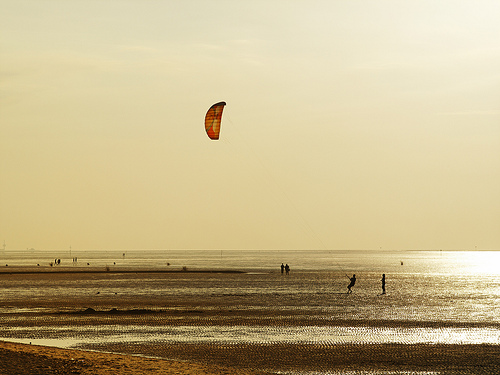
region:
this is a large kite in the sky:
[195, 60, 375, 334]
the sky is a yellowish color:
[0, 2, 494, 249]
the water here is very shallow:
[26, 235, 439, 335]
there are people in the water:
[0, 233, 437, 333]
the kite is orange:
[190, 68, 247, 167]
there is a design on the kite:
[191, 95, 250, 152]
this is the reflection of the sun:
[435, 243, 499, 344]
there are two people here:
[271, 253, 306, 297]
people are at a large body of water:
[3, 235, 473, 371]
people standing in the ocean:
[10, 243, 447, 315]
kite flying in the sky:
[196, 95, 238, 154]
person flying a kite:
[341, 270, 362, 305]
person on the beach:
[375, 269, 391, 300]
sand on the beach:
[29, 348, 91, 373]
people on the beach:
[275, 257, 307, 284]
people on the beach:
[50, 253, 62, 270]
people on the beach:
[65, 254, 80, 272]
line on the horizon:
[295, 242, 432, 259]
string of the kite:
[310, 230, 343, 265]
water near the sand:
[364, 315, 482, 342]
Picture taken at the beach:
[8, 9, 490, 356]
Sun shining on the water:
[400, 228, 499, 319]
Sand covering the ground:
[9, 343, 156, 374]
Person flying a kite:
[197, 93, 363, 299]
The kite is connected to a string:
[210, 102, 354, 289]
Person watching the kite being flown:
[372, 258, 391, 305]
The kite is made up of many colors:
[197, 88, 239, 150]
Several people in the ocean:
[23, 234, 140, 264]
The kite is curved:
[197, 83, 237, 150]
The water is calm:
[159, 239, 445, 266]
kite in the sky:
[192, 95, 232, 146]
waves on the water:
[225, 305, 357, 346]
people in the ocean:
[335, 260, 392, 300]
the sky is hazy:
[267, 168, 345, 217]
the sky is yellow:
[423, 203, 491, 245]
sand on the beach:
[35, 353, 103, 367]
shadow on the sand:
[13, 350, 48, 372]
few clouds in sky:
[98, 25, 183, 87]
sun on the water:
[420, 248, 488, 275]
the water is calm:
[205, 288, 248, 325]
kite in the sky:
[192, 71, 229, 175]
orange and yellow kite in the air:
[193, 99, 235, 158]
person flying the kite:
[319, 252, 357, 304]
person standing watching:
[370, 256, 387, 312]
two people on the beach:
[264, 248, 295, 291]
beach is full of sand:
[56, 298, 496, 374]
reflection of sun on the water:
[436, 253, 496, 280]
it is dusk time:
[0, 172, 490, 373]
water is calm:
[236, 250, 397, 265]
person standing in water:
[389, 252, 434, 289]